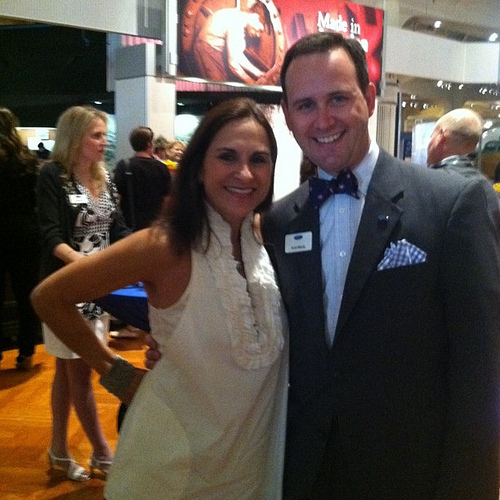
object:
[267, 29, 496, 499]
man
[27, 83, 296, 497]
woman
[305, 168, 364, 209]
bowtie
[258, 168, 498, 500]
suit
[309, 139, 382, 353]
shirt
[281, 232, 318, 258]
nametag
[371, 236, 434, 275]
pocket square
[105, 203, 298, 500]
white top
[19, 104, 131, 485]
woman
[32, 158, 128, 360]
dress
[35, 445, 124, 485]
sandles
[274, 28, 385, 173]
head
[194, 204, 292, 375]
blouse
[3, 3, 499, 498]
photo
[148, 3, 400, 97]
sign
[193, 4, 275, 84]
figure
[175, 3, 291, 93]
wheel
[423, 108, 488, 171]
back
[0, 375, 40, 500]
floor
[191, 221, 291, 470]
front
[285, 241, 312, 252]
writing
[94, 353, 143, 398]
bracelet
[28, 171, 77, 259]
sleeves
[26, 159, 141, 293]
cardigan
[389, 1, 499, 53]
second level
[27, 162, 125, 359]
black and white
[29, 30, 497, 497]
couple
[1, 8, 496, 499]
event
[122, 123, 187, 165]
three people